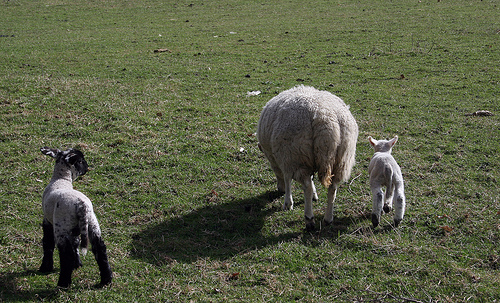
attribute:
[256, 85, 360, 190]
wool — rugged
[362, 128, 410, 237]
lamb — white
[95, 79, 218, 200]
grass — short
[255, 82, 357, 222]
sheep — white, adult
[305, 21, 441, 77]
grass — green, growing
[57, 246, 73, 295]
lamb leg — black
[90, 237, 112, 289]
lamb leg — black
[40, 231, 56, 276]
lamb leg — black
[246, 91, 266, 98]
leaf — brown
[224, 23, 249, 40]
leaf — brown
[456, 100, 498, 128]
leaf — brown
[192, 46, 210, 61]
leaf — brown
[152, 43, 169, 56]
leaf — brown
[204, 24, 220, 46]
leaf — brown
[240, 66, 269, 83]
leaf — brown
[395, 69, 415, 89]
leaf — brown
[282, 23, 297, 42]
leaf — brown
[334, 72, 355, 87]
leaf — brown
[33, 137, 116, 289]
lamb — black, white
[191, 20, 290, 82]
grass — short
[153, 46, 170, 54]
leaf — dry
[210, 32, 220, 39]
leaf — dry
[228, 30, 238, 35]
leaf — dry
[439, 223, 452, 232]
leaf — dry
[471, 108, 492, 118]
leaf — dry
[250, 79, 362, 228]
sheep — grazing, adult, white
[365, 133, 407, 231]
lamb — white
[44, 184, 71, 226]
wool — white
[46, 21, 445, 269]
grass — green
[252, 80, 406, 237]
sheep — adult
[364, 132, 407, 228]
sheep — baby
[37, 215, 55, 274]
fur — black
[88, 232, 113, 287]
fur — black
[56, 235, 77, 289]
fur — black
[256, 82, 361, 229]
fur — white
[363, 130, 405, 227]
fur — white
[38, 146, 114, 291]
fur — white, black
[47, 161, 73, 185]
neck — white